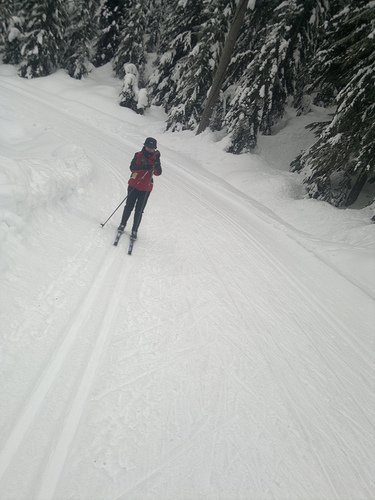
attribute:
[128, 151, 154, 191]
coat — red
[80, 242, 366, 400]
trail — snowy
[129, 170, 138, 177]
pocket — yellow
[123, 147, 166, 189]
jacket — red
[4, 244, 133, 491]
ski trail — curved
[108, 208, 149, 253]
skis — black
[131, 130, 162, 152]
hat — black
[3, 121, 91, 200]
side bank — ungroomed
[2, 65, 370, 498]
trail — groomed